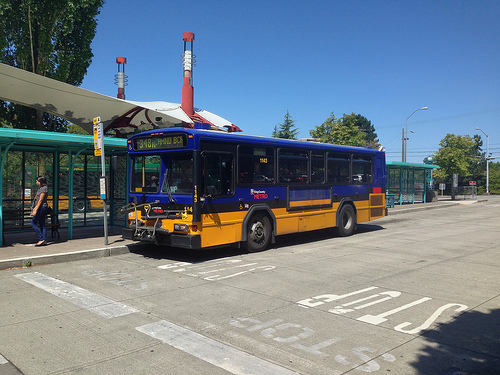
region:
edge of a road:
[64, 249, 69, 256]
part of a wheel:
[258, 234, 269, 252]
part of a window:
[206, 176, 212, 186]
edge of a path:
[156, 252, 191, 332]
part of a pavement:
[407, 195, 416, 224]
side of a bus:
[278, 173, 296, 198]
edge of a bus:
[189, 153, 198, 208]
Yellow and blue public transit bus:
[128, 129, 393, 263]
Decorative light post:
[173, 25, 206, 130]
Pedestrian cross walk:
[16, 252, 494, 372]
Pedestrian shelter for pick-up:
[6, 115, 136, 241]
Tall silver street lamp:
[402, 76, 432, 198]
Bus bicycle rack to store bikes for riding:
[110, 189, 215, 256]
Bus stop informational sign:
[83, 109, 120, 247]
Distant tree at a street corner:
[430, 117, 491, 206]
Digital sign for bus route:
[120, 130, 212, 152]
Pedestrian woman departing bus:
[13, 166, 61, 256]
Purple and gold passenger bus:
[117, 123, 392, 251]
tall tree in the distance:
[430, 130, 485, 200]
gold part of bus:
[128, 197, 384, 245]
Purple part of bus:
[117, 126, 378, 206]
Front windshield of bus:
[121, 126, 196, 202]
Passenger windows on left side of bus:
[233, 136, 383, 201]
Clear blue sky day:
[83, 0, 494, 160]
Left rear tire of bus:
[326, 195, 358, 235]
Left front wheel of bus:
[233, 200, 283, 255]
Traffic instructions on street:
[295, 272, 481, 349]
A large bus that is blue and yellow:
[118, 116, 393, 263]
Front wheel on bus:
[233, 199, 293, 258]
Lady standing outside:
[3, 160, 55, 252]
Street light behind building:
[389, 90, 433, 161]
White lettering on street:
[286, 266, 477, 337]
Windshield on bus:
[126, 147, 196, 197]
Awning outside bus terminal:
[5, 127, 94, 256]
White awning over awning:
[1, 62, 150, 123]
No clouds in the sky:
[206, 6, 443, 126]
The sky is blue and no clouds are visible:
[268, 47, 491, 137]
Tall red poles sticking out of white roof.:
[96, 43, 263, 101]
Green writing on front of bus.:
[136, 135, 186, 155]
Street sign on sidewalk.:
[83, 95, 125, 260]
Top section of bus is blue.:
[151, 139, 451, 183]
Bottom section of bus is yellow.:
[149, 198, 404, 249]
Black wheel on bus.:
[243, 206, 286, 259]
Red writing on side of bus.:
[244, 190, 286, 205]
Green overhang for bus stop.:
[399, 158, 479, 193]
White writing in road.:
[309, 265, 466, 365]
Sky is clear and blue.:
[248, 20, 418, 85]